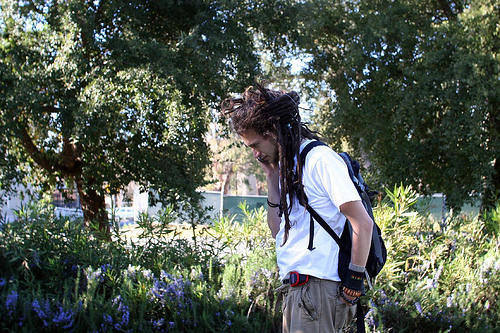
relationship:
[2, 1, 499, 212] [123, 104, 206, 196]
branches of leaves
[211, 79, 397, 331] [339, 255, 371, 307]
man wearing glove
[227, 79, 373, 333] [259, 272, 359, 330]
man wearing pants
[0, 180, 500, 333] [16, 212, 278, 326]
flowers on plants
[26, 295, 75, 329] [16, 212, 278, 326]
flowers on plants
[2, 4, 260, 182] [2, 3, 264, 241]
branches on tree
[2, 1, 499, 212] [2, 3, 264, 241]
branches on tree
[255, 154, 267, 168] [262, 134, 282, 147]
mobile to ear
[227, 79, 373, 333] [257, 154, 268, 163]
man talking on mobile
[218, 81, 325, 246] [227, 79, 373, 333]
dreads on man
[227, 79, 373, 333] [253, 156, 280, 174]
man talking on phone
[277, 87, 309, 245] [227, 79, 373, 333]
dreadlocks on man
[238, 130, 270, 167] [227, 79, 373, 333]
face on man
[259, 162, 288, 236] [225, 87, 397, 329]
arm on man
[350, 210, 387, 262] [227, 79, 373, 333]
arm on man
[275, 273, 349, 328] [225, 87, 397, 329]
pants on man